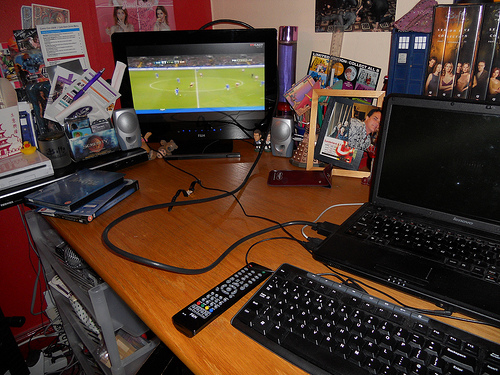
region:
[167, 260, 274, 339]
black television remote control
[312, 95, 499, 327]
black laptop computer turned off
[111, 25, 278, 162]
desktop monitor turned on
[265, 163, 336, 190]
dark red eyeglass case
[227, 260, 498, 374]
black computer keyboard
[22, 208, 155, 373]
clear plastic three tier bin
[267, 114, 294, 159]
silver computer speaker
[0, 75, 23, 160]
open Chinese food container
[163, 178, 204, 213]
wristwatch sitting on desk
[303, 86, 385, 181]
wooden photo frame with picture of man in it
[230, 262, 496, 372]
part of a computer keyboard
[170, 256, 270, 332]
a long black remote control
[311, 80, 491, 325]
part of a black laptop computer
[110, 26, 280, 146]
a small black t.v.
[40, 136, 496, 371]
part of a brown desk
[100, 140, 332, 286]
a long black cord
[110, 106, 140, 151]
a tall gray computer speaker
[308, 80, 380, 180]
a brown picture frame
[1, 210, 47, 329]
part of a red wall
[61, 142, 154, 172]
part of a dvd player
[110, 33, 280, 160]
A computer monitor on the desk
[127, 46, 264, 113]
The monitor is showing a soccer game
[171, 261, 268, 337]
A TV remote control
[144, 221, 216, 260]
The desk is made of wood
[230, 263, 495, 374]
A black computer keyboard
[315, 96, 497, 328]
The laptop is black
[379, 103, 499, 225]
Nothing is on the laptop screen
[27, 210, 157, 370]
The chair is metal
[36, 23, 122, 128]
The papers are messy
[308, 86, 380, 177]
A photo of a boy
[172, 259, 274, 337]
Black television remote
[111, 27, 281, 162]
Small black flatscreen television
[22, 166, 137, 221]
Stack of three DVDs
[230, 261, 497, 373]
Black desktop keyboard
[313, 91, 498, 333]
Black laptop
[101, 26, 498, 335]
Black laptop connected to a television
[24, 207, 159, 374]
Plastic shelving unit under a desk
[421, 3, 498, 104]
Buffy the Vampire Slayer VHS collection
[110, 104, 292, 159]
Pair of small silver computer speakers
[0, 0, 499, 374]
Cluttered computer room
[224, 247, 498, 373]
This is a keyboard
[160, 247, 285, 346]
this is a remote control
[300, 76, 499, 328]
this is a laptop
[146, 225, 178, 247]
this is brown wood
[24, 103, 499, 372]
this is a desk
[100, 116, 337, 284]
these are black cables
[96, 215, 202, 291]
this is a black cable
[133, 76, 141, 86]
this is the color green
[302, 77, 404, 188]
this is a picture frame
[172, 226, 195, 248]
this is the color brown